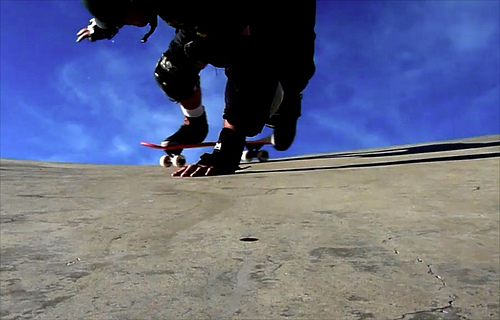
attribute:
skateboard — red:
[140, 138, 271, 165]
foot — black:
[160, 115, 210, 148]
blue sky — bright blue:
[0, 1, 494, 138]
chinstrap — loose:
[142, 17, 160, 45]